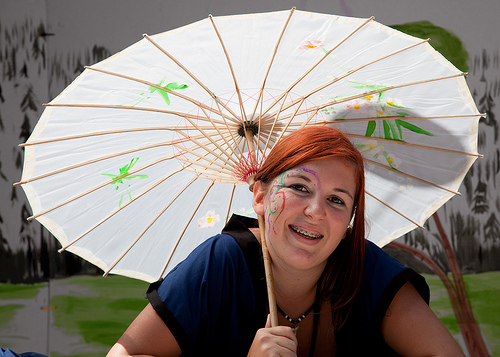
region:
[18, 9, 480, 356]
The girl has an umbrella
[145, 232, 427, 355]
The shirt is blue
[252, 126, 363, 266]
The girl is smiling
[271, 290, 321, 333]
She has a necklace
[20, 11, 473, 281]
The umbrella is white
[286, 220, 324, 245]
She has braces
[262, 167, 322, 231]
She has a painted face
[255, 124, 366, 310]
Her hair is red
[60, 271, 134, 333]
Grass in the background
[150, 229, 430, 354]
The shirt has short sleeves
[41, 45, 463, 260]
the umbrella is transparent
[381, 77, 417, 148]
the leaves are green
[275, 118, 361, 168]
the hair is brown red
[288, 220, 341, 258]
the girl has braces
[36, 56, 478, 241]
the frame is wooden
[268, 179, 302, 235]
the markings are on the face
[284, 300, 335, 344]
the woman has dark necklace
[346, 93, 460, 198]
shadow is on the umbrella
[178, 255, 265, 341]
the shirt is blue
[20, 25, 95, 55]
the wall is grey and white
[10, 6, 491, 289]
a white and green umbrella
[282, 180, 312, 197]
the girl's right eye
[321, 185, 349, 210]
the girl's left eye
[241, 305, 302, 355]
the girl's right hand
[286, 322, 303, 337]
the charm on the girl's necklace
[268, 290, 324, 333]
the necklace around the girl's neck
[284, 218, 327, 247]
the mouth on the girl's face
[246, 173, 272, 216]
the girl's right ear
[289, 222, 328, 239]
the girl's top set of teeth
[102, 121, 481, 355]
a girl wearing a blue shirt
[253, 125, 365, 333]
a woman with red hair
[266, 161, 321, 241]
colorful face paint on a woman's face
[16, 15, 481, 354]
a woman holding a white parasol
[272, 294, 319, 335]
woman wearing a black pendant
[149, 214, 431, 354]
woman wearing a blue shirt with black borders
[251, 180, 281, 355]
the wooden stick of a parasol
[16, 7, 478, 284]
a white parasol with painted flowers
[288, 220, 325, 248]
a woman with braces in her mouth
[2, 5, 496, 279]
a painting on a white wall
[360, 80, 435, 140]
white flowers and green foliage on a parasol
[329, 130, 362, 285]
girls hair is red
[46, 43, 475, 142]
umbrella is white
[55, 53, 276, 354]
hand is holding umbrella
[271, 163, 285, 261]
girls face is painted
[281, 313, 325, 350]
necklace is on her neck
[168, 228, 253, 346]
woman is wearing a blue shirt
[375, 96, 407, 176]
green leaves on umbrella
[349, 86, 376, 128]
orange flowers painted on umbella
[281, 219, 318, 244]
girl is smiling in photo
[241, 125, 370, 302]
girl looking at the camera